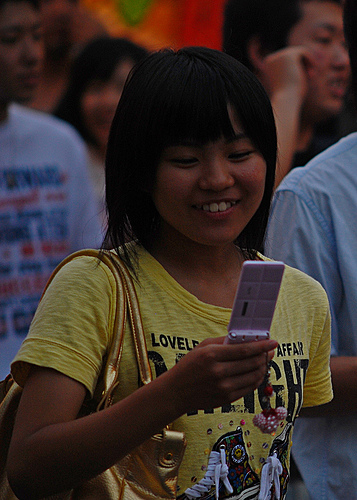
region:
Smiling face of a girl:
[104, 44, 280, 247]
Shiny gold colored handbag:
[0, 243, 190, 499]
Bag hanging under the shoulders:
[0, 246, 189, 499]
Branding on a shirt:
[137, 321, 309, 498]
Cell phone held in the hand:
[179, 256, 289, 410]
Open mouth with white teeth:
[187, 193, 246, 222]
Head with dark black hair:
[87, 40, 284, 277]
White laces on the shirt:
[182, 443, 284, 498]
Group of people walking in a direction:
[0, 0, 355, 498]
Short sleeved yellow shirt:
[8, 236, 335, 498]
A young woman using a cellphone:
[15, 41, 335, 495]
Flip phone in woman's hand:
[214, 243, 291, 379]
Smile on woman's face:
[186, 190, 260, 227]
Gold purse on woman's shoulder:
[1, 225, 187, 498]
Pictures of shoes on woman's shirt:
[177, 423, 291, 498]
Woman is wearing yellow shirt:
[32, 234, 335, 495]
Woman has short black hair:
[72, 36, 302, 306]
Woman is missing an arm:
[281, 253, 336, 450]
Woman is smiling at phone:
[66, 32, 284, 423]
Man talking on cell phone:
[226, 26, 354, 126]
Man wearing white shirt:
[1, 66, 82, 375]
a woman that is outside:
[141, 68, 323, 296]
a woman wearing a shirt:
[117, 191, 356, 428]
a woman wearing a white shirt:
[72, 208, 349, 477]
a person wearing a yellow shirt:
[59, 196, 345, 412]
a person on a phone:
[100, 211, 317, 445]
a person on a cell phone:
[133, 254, 301, 452]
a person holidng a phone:
[196, 257, 346, 433]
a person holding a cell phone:
[199, 224, 272, 408]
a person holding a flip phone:
[166, 191, 348, 492]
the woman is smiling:
[192, 200, 240, 214]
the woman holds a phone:
[228, 260, 284, 341]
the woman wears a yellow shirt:
[15, 259, 333, 494]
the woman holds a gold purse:
[0, 249, 187, 494]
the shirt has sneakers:
[182, 421, 295, 495]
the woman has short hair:
[98, 47, 277, 283]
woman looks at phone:
[172, 145, 252, 168]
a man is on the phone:
[279, 1, 348, 109]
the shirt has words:
[153, 338, 307, 425]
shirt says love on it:
[151, 335, 183, 347]